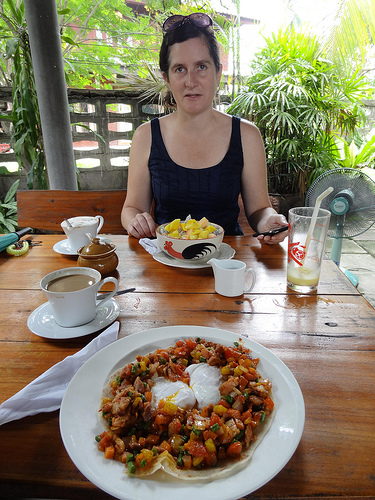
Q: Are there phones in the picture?
A: Yes, there is a phone.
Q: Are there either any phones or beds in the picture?
A: Yes, there is a phone.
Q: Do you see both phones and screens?
A: No, there is a phone but no screens.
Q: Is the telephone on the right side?
A: Yes, the telephone is on the right of the image.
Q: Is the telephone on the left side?
A: No, the telephone is on the right of the image.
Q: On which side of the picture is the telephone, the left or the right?
A: The telephone is on the right of the image.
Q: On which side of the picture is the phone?
A: The phone is on the right of the image.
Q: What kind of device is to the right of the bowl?
A: The device is a phone.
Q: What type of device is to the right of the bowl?
A: The device is a phone.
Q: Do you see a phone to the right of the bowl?
A: Yes, there is a phone to the right of the bowl.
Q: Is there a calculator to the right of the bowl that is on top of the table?
A: No, there is a phone to the right of the bowl.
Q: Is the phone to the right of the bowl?
A: Yes, the phone is to the right of the bowl.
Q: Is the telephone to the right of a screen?
A: No, the telephone is to the right of the bowl.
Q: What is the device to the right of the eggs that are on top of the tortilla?
A: The device is a phone.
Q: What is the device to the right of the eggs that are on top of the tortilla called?
A: The device is a phone.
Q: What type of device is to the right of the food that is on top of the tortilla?
A: The device is a phone.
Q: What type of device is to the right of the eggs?
A: The device is a phone.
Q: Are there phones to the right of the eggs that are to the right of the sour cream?
A: Yes, there is a phone to the right of the eggs.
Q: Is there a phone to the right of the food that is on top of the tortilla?
A: Yes, there is a phone to the right of the eggs.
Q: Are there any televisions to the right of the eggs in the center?
A: No, there is a phone to the right of the eggs.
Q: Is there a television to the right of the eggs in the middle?
A: No, there is a phone to the right of the eggs.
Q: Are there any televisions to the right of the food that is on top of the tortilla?
A: No, there is a phone to the right of the eggs.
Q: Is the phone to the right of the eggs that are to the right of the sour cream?
A: Yes, the phone is to the right of the eggs.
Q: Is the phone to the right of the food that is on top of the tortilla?
A: Yes, the phone is to the right of the eggs.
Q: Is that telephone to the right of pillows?
A: No, the telephone is to the right of the eggs.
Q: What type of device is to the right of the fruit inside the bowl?
A: The device is a phone.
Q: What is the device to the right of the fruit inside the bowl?
A: The device is a phone.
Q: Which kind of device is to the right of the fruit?
A: The device is a phone.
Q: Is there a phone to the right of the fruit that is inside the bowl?
A: Yes, there is a phone to the right of the fruit.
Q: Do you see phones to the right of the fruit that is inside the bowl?
A: Yes, there is a phone to the right of the fruit.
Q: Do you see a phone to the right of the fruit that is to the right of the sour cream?
A: Yes, there is a phone to the right of the fruit.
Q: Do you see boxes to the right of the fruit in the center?
A: No, there is a phone to the right of the fruit.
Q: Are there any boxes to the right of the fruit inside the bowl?
A: No, there is a phone to the right of the fruit.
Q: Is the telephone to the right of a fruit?
A: Yes, the telephone is to the right of a fruit.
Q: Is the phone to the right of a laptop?
A: No, the phone is to the right of a fruit.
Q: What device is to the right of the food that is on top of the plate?
A: The device is a phone.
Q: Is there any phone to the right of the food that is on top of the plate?
A: Yes, there is a phone to the right of the food.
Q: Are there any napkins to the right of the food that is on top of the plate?
A: No, there is a phone to the right of the food.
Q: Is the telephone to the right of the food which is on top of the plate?
A: Yes, the telephone is to the right of the food.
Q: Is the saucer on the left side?
A: Yes, the saucer is on the left of the image.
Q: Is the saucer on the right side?
A: No, the saucer is on the left of the image.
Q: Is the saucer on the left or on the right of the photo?
A: The saucer is on the left of the image.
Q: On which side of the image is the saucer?
A: The saucer is on the left of the image.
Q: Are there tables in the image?
A: Yes, there is a table.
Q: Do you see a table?
A: Yes, there is a table.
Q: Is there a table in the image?
A: Yes, there is a table.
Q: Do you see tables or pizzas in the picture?
A: Yes, there is a table.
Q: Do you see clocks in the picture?
A: No, there are no clocks.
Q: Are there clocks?
A: No, there are no clocks.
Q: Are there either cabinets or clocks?
A: No, there are no clocks or cabinets.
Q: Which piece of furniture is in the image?
A: The piece of furniture is a table.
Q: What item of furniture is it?
A: The piece of furniture is a table.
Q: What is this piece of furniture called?
A: This is a table.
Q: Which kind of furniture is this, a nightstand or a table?
A: This is a table.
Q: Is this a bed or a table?
A: This is a table.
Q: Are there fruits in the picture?
A: Yes, there is a fruit.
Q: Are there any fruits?
A: Yes, there is a fruit.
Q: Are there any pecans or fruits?
A: Yes, there is a fruit.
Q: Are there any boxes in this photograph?
A: No, there are no boxes.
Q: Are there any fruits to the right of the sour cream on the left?
A: Yes, there is a fruit to the right of the sour cream.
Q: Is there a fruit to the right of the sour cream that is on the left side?
A: Yes, there is a fruit to the right of the sour cream.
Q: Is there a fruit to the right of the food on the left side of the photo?
A: Yes, there is a fruit to the right of the sour cream.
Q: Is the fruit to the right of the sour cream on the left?
A: Yes, the fruit is to the right of the sour cream.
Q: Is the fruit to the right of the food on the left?
A: Yes, the fruit is to the right of the sour cream.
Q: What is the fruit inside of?
A: The fruit is inside the bowl.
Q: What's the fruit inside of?
A: The fruit is inside the bowl.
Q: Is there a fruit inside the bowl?
A: Yes, there is a fruit inside the bowl.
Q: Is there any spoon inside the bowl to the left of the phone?
A: No, there is a fruit inside the bowl.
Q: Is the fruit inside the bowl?
A: Yes, the fruit is inside the bowl.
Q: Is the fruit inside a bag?
A: No, the fruit is inside the bowl.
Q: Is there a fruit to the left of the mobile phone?
A: Yes, there is a fruit to the left of the mobile phone.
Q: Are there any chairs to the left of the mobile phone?
A: No, there is a fruit to the left of the mobile phone.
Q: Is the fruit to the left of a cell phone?
A: Yes, the fruit is to the left of a cell phone.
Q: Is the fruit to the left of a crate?
A: No, the fruit is to the left of a cell phone.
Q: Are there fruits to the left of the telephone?
A: Yes, there is a fruit to the left of the telephone.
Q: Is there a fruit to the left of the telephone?
A: Yes, there is a fruit to the left of the telephone.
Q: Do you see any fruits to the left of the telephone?
A: Yes, there is a fruit to the left of the telephone.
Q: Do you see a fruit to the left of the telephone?
A: Yes, there is a fruit to the left of the telephone.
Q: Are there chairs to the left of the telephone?
A: No, there is a fruit to the left of the telephone.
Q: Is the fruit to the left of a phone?
A: Yes, the fruit is to the left of a phone.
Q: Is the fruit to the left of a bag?
A: No, the fruit is to the left of a phone.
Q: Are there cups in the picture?
A: Yes, there is a cup.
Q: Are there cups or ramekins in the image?
A: Yes, there is a cup.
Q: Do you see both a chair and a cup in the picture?
A: No, there is a cup but no chairs.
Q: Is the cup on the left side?
A: Yes, the cup is on the left of the image.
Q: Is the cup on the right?
A: No, the cup is on the left of the image.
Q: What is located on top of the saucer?
A: The cup is on top of the saucer.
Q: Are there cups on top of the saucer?
A: Yes, there is a cup on top of the saucer.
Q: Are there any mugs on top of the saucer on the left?
A: No, there is a cup on top of the saucer.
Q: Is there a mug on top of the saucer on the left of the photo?
A: No, there is a cup on top of the saucer.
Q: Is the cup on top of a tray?
A: No, the cup is on top of the saucer.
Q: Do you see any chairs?
A: No, there are no chairs.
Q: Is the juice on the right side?
A: Yes, the juice is on the right of the image.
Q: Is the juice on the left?
A: No, the juice is on the right of the image.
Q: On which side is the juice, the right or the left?
A: The juice is on the right of the image.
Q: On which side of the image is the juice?
A: The juice is on the right of the image.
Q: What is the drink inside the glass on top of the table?
A: The drink is juice.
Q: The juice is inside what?
A: The juice is inside the glass.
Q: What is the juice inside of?
A: The juice is inside the glass.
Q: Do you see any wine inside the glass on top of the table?
A: No, there is juice inside the glass.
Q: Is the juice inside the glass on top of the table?
A: Yes, the juice is inside the glass.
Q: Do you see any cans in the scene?
A: No, there are no cans.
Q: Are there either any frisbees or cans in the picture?
A: No, there are no cans or frisbees.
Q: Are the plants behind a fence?
A: No, the plants are behind the person.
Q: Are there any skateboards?
A: No, there are no skateboards.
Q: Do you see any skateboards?
A: No, there are no skateboards.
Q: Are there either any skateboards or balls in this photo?
A: No, there are no skateboards or balls.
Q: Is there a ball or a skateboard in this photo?
A: No, there are no skateboards or balls.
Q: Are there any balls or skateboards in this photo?
A: No, there are no skateboards or balls.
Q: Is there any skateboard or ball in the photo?
A: No, there are no skateboards or balls.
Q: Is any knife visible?
A: No, there are no knives.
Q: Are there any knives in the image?
A: No, there are no knives.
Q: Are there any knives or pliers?
A: No, there are no knives or pliers.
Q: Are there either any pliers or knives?
A: No, there are no knives or pliers.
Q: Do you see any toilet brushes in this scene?
A: No, there are no toilet brushes.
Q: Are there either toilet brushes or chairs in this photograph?
A: No, there are no toilet brushes or chairs.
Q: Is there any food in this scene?
A: Yes, there is food.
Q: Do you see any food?
A: Yes, there is food.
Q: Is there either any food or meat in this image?
A: Yes, there is food.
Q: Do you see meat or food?
A: Yes, there is food.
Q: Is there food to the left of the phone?
A: Yes, there is food to the left of the phone.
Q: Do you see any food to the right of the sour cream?
A: Yes, there is food to the right of the sour cream.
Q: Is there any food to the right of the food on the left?
A: Yes, there is food to the right of the sour cream.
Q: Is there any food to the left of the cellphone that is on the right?
A: Yes, there is food to the left of the cell phone.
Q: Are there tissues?
A: No, there are no tissues.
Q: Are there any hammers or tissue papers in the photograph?
A: No, there are no tissue papers or hammers.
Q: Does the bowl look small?
A: Yes, the bowl is small.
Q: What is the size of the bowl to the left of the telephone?
A: The bowl is small.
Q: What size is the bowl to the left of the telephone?
A: The bowl is small.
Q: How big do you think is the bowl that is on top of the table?
A: The bowl is small.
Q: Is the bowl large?
A: No, the bowl is small.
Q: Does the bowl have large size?
A: No, the bowl is small.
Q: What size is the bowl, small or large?
A: The bowl is small.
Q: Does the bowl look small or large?
A: The bowl is small.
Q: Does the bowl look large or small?
A: The bowl is small.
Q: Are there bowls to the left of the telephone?
A: Yes, there is a bowl to the left of the telephone.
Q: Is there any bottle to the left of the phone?
A: No, there is a bowl to the left of the phone.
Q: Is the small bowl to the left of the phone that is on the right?
A: Yes, the bowl is to the left of the phone.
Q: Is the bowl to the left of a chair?
A: No, the bowl is to the left of the phone.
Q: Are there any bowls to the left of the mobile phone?
A: Yes, there is a bowl to the left of the mobile phone.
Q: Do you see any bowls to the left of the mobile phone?
A: Yes, there is a bowl to the left of the mobile phone.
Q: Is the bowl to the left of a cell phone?
A: Yes, the bowl is to the left of a cell phone.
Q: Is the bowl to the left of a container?
A: No, the bowl is to the left of a cell phone.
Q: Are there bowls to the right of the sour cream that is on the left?
A: Yes, there is a bowl to the right of the sour cream.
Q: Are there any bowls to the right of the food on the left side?
A: Yes, there is a bowl to the right of the sour cream.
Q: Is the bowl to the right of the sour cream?
A: Yes, the bowl is to the right of the sour cream.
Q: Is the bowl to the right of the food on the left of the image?
A: Yes, the bowl is to the right of the sour cream.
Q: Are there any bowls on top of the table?
A: Yes, there is a bowl on top of the table.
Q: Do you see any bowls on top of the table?
A: Yes, there is a bowl on top of the table.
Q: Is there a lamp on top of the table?
A: No, there is a bowl on top of the table.